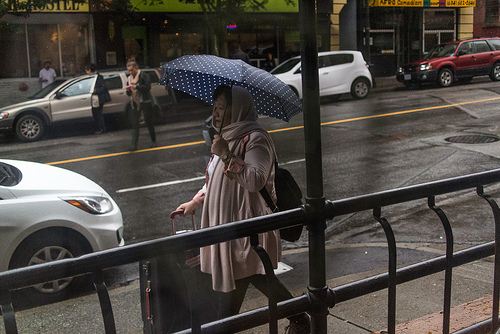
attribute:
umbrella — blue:
[161, 53, 305, 126]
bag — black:
[266, 162, 305, 237]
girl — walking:
[119, 53, 165, 143]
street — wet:
[67, 78, 364, 173]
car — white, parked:
[252, 28, 380, 107]